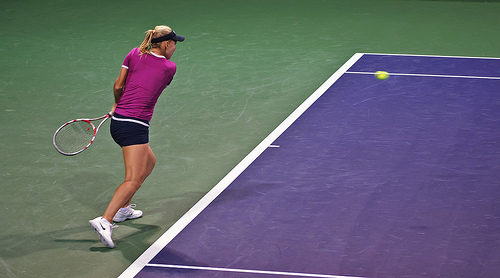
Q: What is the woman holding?
A: Tennis racquet,.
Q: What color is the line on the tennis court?
A: White.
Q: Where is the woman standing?
A: Tennis court.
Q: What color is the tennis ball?
A: Yellow.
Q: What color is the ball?
A: Yellow.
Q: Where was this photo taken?
A: Tennis court.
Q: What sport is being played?
A: Tennis.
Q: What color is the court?
A: Purple.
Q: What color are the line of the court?
A: White.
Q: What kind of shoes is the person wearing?
A: Nike.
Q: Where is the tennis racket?
A: In the person's hand.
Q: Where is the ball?
A: In the air.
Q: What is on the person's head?
A: Visor.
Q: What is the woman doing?
A: Playing tennis.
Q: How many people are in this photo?
A: 1.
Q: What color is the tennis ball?
A: Green.